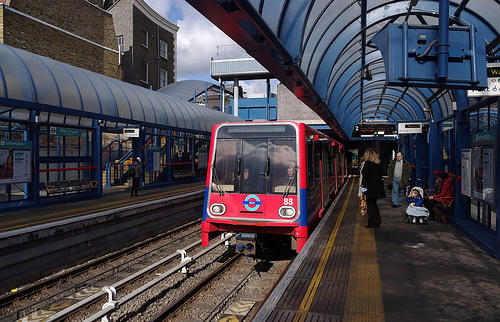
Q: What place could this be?
A: It is a train station.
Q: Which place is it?
A: It is a train station.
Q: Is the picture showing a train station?
A: Yes, it is showing a train station.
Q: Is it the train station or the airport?
A: It is the train station.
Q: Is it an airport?
A: No, it is a train station.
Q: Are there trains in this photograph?
A: Yes, there is a train.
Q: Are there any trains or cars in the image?
A: Yes, there is a train.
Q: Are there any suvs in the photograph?
A: No, there are no suvs.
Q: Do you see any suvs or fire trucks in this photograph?
A: No, there are no suvs or fire trucks.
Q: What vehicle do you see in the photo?
A: The vehicle is a train.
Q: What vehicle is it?
A: The vehicle is a train.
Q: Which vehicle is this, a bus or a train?
A: That is a train.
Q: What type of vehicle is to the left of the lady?
A: The vehicle is a train.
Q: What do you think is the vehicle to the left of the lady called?
A: The vehicle is a train.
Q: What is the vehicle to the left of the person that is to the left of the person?
A: The vehicle is a train.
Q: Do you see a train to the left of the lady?
A: Yes, there is a train to the left of the lady.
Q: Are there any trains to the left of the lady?
A: Yes, there is a train to the left of the lady.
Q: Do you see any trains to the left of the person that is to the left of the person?
A: Yes, there is a train to the left of the lady.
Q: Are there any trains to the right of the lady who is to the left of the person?
A: No, the train is to the left of the lady.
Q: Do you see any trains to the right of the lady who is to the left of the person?
A: No, the train is to the left of the lady.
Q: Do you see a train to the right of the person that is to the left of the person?
A: No, the train is to the left of the lady.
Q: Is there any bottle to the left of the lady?
A: No, there is a train to the left of the lady.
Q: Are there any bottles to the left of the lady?
A: No, there is a train to the left of the lady.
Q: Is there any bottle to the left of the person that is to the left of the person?
A: No, there is a train to the left of the lady.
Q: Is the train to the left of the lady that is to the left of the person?
A: Yes, the train is to the left of the lady.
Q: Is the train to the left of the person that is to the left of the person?
A: Yes, the train is to the left of the lady.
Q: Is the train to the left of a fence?
A: No, the train is to the left of the lady.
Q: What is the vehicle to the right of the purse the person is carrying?
A: The vehicle is a train.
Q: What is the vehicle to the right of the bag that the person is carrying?
A: The vehicle is a train.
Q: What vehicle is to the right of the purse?
A: The vehicle is a train.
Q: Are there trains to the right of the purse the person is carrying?
A: Yes, there is a train to the right of the purse.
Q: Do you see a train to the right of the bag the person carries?
A: Yes, there is a train to the right of the purse.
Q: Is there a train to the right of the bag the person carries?
A: Yes, there is a train to the right of the purse.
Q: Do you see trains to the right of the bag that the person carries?
A: Yes, there is a train to the right of the purse.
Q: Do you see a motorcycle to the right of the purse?
A: No, there is a train to the right of the purse.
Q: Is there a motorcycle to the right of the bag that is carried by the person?
A: No, there is a train to the right of the purse.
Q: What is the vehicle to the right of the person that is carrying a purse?
A: The vehicle is a train.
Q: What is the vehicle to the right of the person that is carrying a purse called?
A: The vehicle is a train.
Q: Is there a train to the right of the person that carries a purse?
A: Yes, there is a train to the right of the person.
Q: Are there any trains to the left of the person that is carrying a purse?
A: No, the train is to the right of the person.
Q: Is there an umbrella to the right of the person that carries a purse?
A: No, there is a train to the right of the person.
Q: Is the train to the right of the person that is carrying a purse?
A: Yes, the train is to the right of the person.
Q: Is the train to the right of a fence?
A: No, the train is to the right of the person.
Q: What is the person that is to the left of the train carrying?
A: The person is carrying a purse.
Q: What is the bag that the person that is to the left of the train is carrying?
A: The bag is a purse.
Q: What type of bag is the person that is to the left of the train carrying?
A: The person is carrying a purse.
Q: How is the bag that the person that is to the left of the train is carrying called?
A: The bag is a purse.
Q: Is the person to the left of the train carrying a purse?
A: Yes, the person is carrying a purse.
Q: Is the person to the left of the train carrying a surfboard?
A: No, the person is carrying a purse.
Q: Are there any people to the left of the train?
A: Yes, there is a person to the left of the train.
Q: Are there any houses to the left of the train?
A: No, there is a person to the left of the train.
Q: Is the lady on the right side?
A: Yes, the lady is on the right of the image.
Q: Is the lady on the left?
A: No, the lady is on the right of the image.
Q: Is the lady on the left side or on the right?
A: The lady is on the right of the image.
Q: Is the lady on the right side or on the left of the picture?
A: The lady is on the right of the image.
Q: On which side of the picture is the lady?
A: The lady is on the right of the image.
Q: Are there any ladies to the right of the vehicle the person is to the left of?
A: Yes, there is a lady to the right of the train.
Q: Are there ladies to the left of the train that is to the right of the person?
A: No, the lady is to the right of the train.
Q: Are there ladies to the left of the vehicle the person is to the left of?
A: No, the lady is to the right of the train.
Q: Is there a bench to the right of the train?
A: No, there is a lady to the right of the train.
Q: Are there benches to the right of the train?
A: No, there is a lady to the right of the train.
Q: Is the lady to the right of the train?
A: Yes, the lady is to the right of the train.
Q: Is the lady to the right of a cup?
A: No, the lady is to the right of the train.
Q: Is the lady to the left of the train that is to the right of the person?
A: No, the lady is to the right of the train.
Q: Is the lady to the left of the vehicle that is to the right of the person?
A: No, the lady is to the right of the train.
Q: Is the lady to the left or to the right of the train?
A: The lady is to the right of the train.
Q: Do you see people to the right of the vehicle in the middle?
A: Yes, there is a person to the right of the train.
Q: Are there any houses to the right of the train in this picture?
A: No, there is a person to the right of the train.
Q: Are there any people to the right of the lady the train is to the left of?
A: Yes, there is a person to the right of the lady.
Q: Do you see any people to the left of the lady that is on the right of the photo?
A: No, the person is to the right of the lady.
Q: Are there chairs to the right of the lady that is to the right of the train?
A: No, there is a person to the right of the lady.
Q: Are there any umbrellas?
A: No, there are no umbrellas.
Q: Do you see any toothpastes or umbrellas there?
A: No, there are no umbrellas or toothpastes.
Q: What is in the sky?
A: The clouds are in the sky.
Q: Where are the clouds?
A: The clouds are in the sky.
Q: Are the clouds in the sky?
A: Yes, the clouds are in the sky.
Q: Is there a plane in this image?
A: No, there are no airplanes.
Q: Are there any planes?
A: No, there are no planes.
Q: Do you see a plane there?
A: No, there are no airplanes.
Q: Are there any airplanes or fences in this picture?
A: No, there are no airplanes or fences.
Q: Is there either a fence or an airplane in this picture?
A: No, there are no airplanes or fences.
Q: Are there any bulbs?
A: No, there are no bulbs.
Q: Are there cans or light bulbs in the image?
A: No, there are no light bulbs or cans.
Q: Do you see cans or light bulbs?
A: No, there are no light bulbs or cans.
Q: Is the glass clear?
A: Yes, the glass is clear.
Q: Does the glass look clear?
A: Yes, the glass is clear.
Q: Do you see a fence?
A: No, there are no fences.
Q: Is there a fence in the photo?
A: No, there are no fences.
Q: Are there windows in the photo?
A: Yes, there is a window.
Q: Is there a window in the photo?
A: Yes, there is a window.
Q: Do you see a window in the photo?
A: Yes, there is a window.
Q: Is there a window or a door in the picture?
A: Yes, there is a window.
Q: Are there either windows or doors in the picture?
A: Yes, there is a window.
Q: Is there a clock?
A: No, there are no clocks.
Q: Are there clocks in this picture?
A: No, there are no clocks.